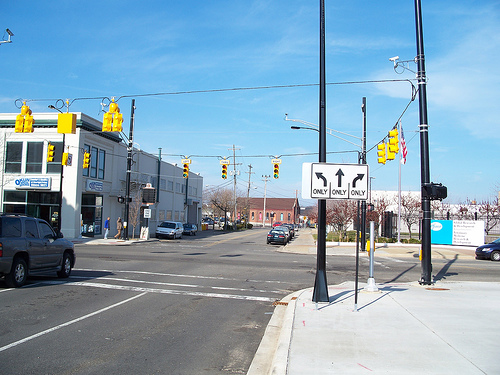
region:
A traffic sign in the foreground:
[302, 156, 371, 313]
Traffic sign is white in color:
[305, 157, 369, 310]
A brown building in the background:
[232, 188, 303, 229]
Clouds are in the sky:
[2, 8, 498, 193]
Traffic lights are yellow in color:
[13, 88, 414, 188]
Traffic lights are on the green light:
[171, 157, 299, 184]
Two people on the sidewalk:
[96, 209, 128, 239]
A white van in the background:
[146, 210, 186, 247]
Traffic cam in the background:
[382, 50, 406, 71]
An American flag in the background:
[393, 122, 411, 171]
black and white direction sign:
[308, 161, 371, 198]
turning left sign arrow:
[311, 164, 331, 198]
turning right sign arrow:
[347, 165, 367, 197]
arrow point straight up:
[330, 167, 350, 198]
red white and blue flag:
[395, 120, 412, 170]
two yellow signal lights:
[374, 125, 400, 164]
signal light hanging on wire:
[93, 90, 133, 135]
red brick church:
[231, 193, 303, 225]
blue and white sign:
[430, 216, 486, 246]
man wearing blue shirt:
[97, 214, 114, 238]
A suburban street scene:
[5, 4, 488, 364]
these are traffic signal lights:
[11, 97, 408, 182]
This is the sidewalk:
[254, 282, 497, 373]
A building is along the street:
[1, 108, 208, 242]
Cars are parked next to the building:
[154, 210, 201, 241]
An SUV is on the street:
[0, 207, 78, 289]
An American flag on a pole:
[394, 118, 410, 249]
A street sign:
[305, 160, 373, 202]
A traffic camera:
[384, 51, 406, 71]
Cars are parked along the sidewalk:
[264, 220, 315, 253]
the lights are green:
[148, 131, 290, 210]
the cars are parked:
[255, 205, 300, 261]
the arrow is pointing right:
[348, 161, 368, 192]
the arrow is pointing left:
[292, 151, 331, 195]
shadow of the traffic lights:
[142, 234, 252, 269]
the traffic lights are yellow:
[0, 103, 134, 148]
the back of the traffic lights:
[0, 94, 139, 159]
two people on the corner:
[87, 204, 135, 242]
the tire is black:
[2, 256, 32, 298]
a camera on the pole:
[369, 45, 420, 90]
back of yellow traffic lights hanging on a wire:
[9, 98, 136, 143]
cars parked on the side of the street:
[261, 215, 295, 252]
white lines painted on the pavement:
[79, 260, 282, 311]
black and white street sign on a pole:
[303, 156, 376, 211]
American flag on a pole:
[396, 119, 408, 248]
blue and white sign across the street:
[422, 206, 487, 250]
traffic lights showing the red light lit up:
[171, 151, 288, 191]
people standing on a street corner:
[96, 206, 128, 245]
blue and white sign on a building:
[14, 174, 57, 193]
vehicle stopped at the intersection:
[0, 203, 84, 285]